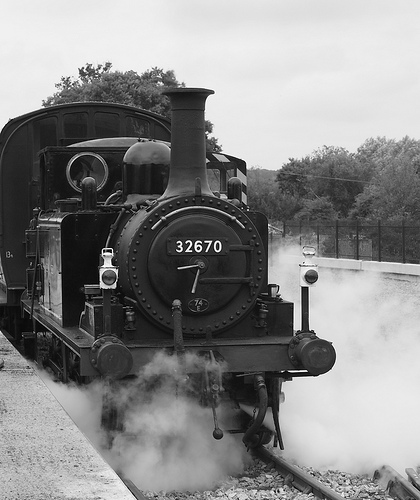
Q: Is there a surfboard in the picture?
A: No, there are no surfboards.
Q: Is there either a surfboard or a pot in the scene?
A: No, there are no surfboards or pots.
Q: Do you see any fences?
A: Yes, there is a fence.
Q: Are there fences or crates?
A: Yes, there is a fence.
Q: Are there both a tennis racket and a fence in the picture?
A: No, there is a fence but no rackets.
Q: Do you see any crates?
A: No, there are no crates.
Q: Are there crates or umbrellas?
A: No, there are no crates or umbrellas.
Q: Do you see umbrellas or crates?
A: No, there are no crates or umbrellas.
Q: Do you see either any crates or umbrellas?
A: No, there are no crates or umbrellas.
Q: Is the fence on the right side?
A: Yes, the fence is on the right of the image.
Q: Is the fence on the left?
A: No, the fence is on the right of the image.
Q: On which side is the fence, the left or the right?
A: The fence is on the right of the image.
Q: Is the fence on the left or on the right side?
A: The fence is on the right of the image.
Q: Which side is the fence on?
A: The fence is on the right of the image.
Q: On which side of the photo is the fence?
A: The fence is on the right of the image.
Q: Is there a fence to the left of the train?
A: No, the fence is to the right of the train.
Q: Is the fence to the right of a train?
A: Yes, the fence is to the right of a train.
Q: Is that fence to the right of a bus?
A: No, the fence is to the right of a train.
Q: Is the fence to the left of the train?
A: No, the fence is to the right of the train.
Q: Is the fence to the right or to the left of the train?
A: The fence is to the right of the train.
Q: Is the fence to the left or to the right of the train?
A: The fence is to the right of the train.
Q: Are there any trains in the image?
A: Yes, there is a train.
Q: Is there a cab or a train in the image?
A: Yes, there is a train.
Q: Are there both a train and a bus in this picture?
A: No, there is a train but no buses.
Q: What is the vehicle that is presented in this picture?
A: The vehicle is a train.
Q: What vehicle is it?
A: The vehicle is a train.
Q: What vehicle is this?
A: This is a train.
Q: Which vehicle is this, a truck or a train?
A: This is a train.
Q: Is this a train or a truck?
A: This is a train.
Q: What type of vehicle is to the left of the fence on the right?
A: The vehicle is a train.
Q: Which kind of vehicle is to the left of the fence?
A: The vehicle is a train.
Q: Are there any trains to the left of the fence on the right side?
A: Yes, there is a train to the left of the fence.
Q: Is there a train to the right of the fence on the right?
A: No, the train is to the left of the fence.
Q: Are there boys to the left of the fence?
A: No, there is a train to the left of the fence.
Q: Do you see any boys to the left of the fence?
A: No, there is a train to the left of the fence.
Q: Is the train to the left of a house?
A: No, the train is to the left of a fence.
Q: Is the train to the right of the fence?
A: No, the train is to the left of the fence.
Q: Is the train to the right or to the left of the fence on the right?
A: The train is to the left of the fence.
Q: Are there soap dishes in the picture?
A: No, there are no soap dishes.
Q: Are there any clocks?
A: No, there are no clocks.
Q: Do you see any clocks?
A: No, there are no clocks.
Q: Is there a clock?
A: No, there are no clocks.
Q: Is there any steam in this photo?
A: Yes, there is steam.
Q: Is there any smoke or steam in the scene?
A: Yes, there is steam.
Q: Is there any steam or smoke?
A: Yes, there is steam.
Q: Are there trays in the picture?
A: No, there are no trays.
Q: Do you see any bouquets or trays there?
A: No, there are no trays or bouquets.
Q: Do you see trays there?
A: No, there are no trays.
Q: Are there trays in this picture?
A: No, there are no trays.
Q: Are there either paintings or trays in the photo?
A: No, there are no trays or paintings.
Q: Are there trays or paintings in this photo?
A: No, there are no trays or paintings.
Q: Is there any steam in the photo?
A: Yes, there is steam.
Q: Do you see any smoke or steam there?
A: Yes, there is steam.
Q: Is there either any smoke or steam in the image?
A: Yes, there is steam.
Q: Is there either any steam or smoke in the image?
A: Yes, there is steam.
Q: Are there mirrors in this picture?
A: No, there are no mirrors.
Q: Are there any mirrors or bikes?
A: No, there are no mirrors or bikes.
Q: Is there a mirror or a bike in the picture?
A: No, there are no mirrors or bikes.